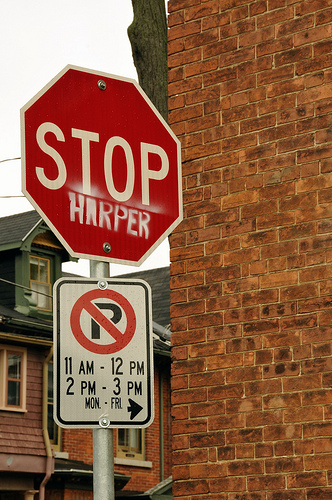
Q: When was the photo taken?
A: Daytime.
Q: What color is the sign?
A: Red.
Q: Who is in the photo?
A: Nobody.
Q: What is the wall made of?
A: Brick.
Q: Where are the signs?
A: On the pole.